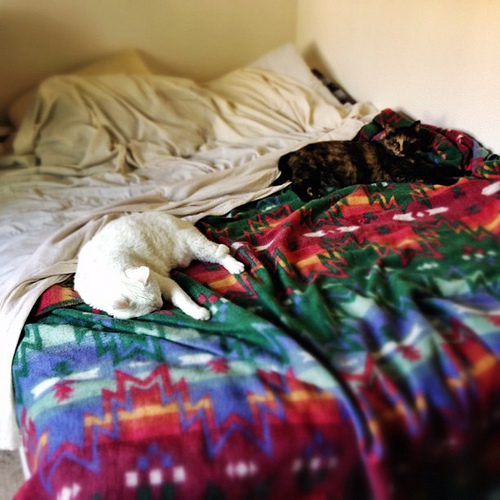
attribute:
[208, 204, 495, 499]
blanket — multi colored, soft 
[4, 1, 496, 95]
walls — cream, white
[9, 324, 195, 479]
blanket — colored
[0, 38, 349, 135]
pillows — white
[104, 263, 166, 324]
cat ears — white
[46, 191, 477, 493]
blankets — red, blue, green, yellow , white